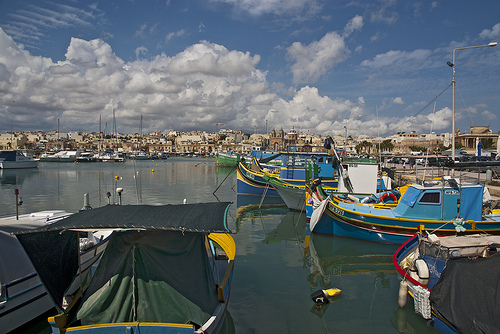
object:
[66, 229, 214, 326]
tarp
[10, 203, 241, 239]
tarp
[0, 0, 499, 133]
sky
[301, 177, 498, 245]
boat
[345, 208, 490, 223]
stripe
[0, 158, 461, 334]
water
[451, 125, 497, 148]
buildings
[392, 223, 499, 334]
boats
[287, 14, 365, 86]
clouds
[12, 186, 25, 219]
light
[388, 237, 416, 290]
trim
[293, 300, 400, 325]
object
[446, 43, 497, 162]
light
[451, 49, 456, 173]
pole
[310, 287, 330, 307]
buoy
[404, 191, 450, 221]
cabin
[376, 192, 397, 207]
life preserver